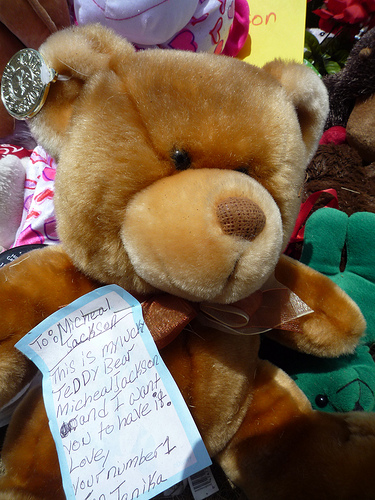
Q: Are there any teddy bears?
A: Yes, there is a teddy bear.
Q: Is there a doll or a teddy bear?
A: Yes, there is a teddy bear.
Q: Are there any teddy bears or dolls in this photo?
A: Yes, there is a teddy bear.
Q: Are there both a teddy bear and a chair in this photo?
A: No, there is a teddy bear but no chairs.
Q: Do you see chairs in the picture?
A: No, there are no chairs.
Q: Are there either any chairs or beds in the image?
A: No, there are no chairs or beds.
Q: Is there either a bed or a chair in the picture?
A: No, there are no chairs or beds.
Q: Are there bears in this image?
A: Yes, there is a bear.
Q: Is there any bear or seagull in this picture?
A: Yes, there is a bear.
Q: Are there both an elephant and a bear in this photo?
A: No, there is a bear but no elephants.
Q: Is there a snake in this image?
A: No, there are no snakes.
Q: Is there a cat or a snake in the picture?
A: No, there are no snakes or cats.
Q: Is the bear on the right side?
A: Yes, the bear is on the right of the image.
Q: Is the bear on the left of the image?
A: No, the bear is on the right of the image.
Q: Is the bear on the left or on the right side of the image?
A: The bear is on the right of the image.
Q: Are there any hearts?
A: Yes, there is a heart.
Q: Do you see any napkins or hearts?
A: Yes, there is a heart.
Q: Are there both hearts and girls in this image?
A: No, there is a heart but no girls.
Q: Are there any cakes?
A: No, there are no cakes.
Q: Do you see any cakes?
A: No, there are no cakes.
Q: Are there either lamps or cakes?
A: No, there are no cakes or lamps.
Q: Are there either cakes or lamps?
A: No, there are no cakes or lamps.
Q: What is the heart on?
A: The heart is on the teddy bear.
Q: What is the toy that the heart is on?
A: The toy is a teddy bear.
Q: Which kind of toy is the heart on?
A: The heart is on the teddy bear.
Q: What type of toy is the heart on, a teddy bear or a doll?
A: The heart is on a teddy bear.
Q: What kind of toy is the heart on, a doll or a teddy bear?
A: The heart is on a teddy bear.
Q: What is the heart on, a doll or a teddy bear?
A: The heart is on a teddy bear.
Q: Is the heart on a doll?
A: No, the heart is on the teddy bear.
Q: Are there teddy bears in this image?
A: Yes, there is a teddy bear.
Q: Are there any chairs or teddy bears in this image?
A: Yes, there is a teddy bear.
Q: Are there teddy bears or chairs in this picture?
A: Yes, there is a teddy bear.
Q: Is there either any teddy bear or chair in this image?
A: Yes, there is a teddy bear.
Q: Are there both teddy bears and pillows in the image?
A: No, there is a teddy bear but no pillows.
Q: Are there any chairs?
A: No, there are no chairs.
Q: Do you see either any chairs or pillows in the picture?
A: No, there are no chairs or pillows.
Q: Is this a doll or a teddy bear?
A: This is a teddy bear.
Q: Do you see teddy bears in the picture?
A: Yes, there is a teddy bear.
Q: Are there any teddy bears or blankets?
A: Yes, there is a teddy bear.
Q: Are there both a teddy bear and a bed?
A: No, there is a teddy bear but no beds.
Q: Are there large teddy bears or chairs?
A: Yes, there is a large teddy bear.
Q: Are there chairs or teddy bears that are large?
A: Yes, the teddy bear is large.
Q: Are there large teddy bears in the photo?
A: Yes, there is a large teddy bear.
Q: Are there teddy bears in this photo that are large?
A: Yes, there is a large teddy bear.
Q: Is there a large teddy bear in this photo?
A: Yes, there is a large teddy bear.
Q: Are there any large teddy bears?
A: Yes, there is a large teddy bear.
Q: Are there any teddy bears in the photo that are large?
A: Yes, there is a teddy bear that is large.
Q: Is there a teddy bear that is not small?
A: Yes, there is a large teddy bear.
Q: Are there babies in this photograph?
A: No, there are no babies.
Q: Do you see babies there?
A: No, there are no babies.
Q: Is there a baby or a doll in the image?
A: No, there are no babies or dolls.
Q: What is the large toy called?
A: The toy is a teddy bear.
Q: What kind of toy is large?
A: The toy is a teddy bear.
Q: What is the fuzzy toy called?
A: The toy is a teddy bear.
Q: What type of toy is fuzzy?
A: The toy is a teddy bear.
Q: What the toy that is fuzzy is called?
A: The toy is a teddy bear.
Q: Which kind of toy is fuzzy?
A: The toy is a teddy bear.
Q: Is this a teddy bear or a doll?
A: This is a teddy bear.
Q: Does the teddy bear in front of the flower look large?
A: Yes, the teddy bear is large.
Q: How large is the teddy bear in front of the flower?
A: The teddy bear is large.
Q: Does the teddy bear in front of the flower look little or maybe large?
A: The teddy bear is large.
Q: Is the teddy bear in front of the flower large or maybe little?
A: The teddy bear is large.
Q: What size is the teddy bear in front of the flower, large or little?
A: The teddy bear is large.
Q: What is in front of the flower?
A: The teddy bear is in front of the flower.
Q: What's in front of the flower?
A: The teddy bear is in front of the flower.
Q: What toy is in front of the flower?
A: The toy is a teddy bear.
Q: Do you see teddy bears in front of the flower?
A: Yes, there is a teddy bear in front of the flower.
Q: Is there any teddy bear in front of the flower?
A: Yes, there is a teddy bear in front of the flower.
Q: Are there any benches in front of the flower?
A: No, there is a teddy bear in front of the flower.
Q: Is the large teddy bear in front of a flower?
A: Yes, the teddy bear is in front of a flower.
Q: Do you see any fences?
A: No, there are no fences.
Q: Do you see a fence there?
A: No, there are no fences.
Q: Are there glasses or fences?
A: No, there are no fences or glasses.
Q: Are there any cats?
A: No, there are no cats.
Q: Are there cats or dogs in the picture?
A: No, there are no cats or dogs.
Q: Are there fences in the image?
A: No, there are no fences.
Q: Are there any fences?
A: No, there are no fences.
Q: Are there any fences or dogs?
A: No, there are no fences or dogs.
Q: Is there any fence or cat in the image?
A: No, there are no cats or fences.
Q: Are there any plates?
A: No, there are no plates.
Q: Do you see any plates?
A: No, there are no plates.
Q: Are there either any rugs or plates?
A: No, there are no plates or rugs.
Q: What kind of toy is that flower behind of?
A: The flower is behind the teddy bear.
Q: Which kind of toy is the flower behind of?
A: The flower is behind the teddy bear.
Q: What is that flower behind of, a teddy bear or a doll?
A: The flower is behind a teddy bear.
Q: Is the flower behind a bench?
A: No, the flower is behind the teddy bear.